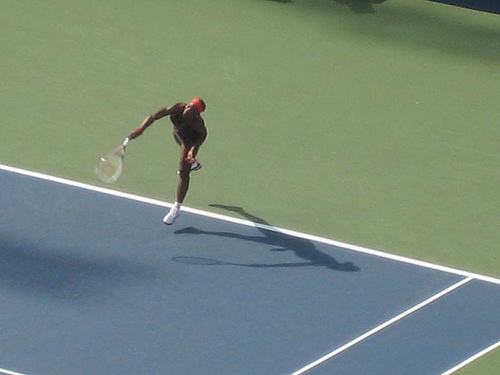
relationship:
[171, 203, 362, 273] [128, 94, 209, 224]
shadow of player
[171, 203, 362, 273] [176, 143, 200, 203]
shadow of left leg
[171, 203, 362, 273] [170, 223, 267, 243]
shadow of leg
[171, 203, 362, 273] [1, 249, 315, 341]
shadow on court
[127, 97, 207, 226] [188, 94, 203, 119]
man has headband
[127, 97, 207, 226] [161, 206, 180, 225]
man wearing shoe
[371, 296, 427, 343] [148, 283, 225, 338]
line on court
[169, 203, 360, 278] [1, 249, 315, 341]
shadow on court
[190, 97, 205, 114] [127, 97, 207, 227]
headband is on man